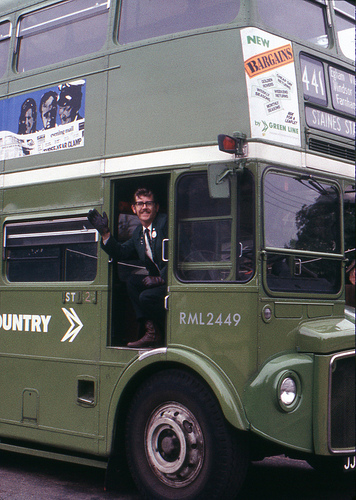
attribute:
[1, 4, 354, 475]
bus — green, double-decker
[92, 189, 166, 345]
man — waving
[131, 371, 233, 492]
wheel — dirty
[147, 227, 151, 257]
tie — black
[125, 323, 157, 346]
boot — brown